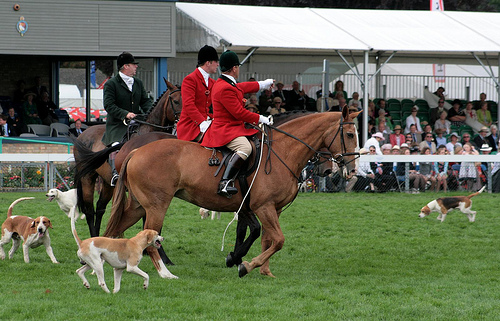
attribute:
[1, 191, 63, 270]
dog — white, brown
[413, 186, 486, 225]
dog — in background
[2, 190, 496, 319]
grass — green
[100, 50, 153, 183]
man — white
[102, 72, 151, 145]
coat — black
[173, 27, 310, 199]
coats — red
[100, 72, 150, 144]
jacket — black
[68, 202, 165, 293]
dog — brown, white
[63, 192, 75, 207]
dog's coat — white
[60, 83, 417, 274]
horse — brown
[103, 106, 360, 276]
horse — brown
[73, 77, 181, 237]
horse — brown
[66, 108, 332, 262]
horse — brown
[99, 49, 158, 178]
man — black-dressed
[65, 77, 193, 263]
horse — black, brown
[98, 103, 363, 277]
brown horse — large, muscular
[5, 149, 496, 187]
fence — small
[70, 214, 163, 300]
dog — light brown, white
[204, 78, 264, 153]
riding outfit — red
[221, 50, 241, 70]
hat — black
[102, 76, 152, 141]
coat — black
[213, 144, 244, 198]
boot — black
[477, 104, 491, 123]
vest — green